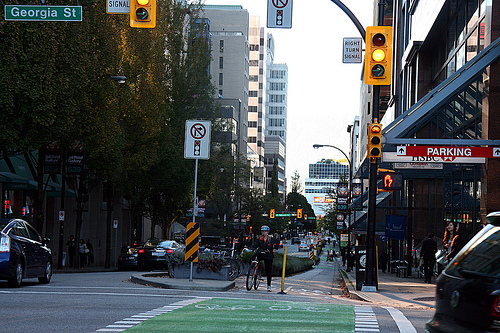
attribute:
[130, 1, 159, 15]
light — yellow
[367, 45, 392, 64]
light — yellow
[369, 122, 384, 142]
light — yellow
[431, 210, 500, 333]
car — black, compact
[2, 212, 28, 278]
car — black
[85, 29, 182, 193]
tree — green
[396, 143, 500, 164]
banner — red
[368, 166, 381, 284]
post — black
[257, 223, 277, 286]
person — riding, stopped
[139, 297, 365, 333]
road — green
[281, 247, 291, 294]
post — yellow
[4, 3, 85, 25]
sign — green, white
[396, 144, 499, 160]
sign — red, white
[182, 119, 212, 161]
sign — red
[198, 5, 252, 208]
building — high, tall, white